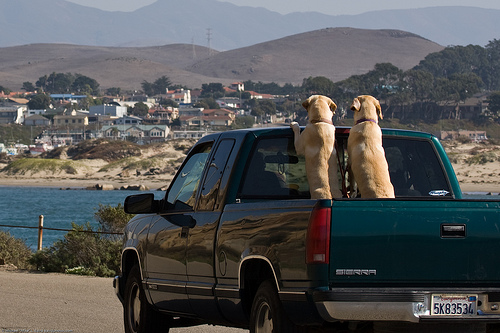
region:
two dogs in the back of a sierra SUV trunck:
[295, 88, 415, 214]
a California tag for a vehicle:
[431, 287, 493, 319]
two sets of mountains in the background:
[0, 0, 455, 100]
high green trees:
[290, 45, 498, 128]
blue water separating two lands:
[0, 189, 161, 254]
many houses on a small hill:
[0, 73, 235, 146]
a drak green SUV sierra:
[110, 105, 487, 321]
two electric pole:
[187, 20, 213, 65]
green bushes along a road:
[2, 198, 131, 269]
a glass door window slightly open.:
[150, 142, 225, 236]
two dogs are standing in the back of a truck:
[285, 89, 404, 198]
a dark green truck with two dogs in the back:
[101, 89, 498, 329]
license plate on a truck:
[422, 289, 482, 320]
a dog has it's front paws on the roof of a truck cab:
[288, 91, 347, 200]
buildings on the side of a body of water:
[0, 78, 306, 163]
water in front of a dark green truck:
[1, 179, 168, 255]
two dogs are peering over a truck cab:
[283, 91, 403, 202]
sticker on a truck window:
[424, 186, 451, 200]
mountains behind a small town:
[0, 0, 499, 82]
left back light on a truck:
[300, 204, 335, 270]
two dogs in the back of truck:
[270, 75, 446, 214]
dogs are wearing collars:
[298, 97, 389, 160]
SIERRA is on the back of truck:
[213, 200, 423, 297]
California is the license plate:
[426, 284, 494, 331]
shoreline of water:
[11, 164, 110, 202]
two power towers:
[184, 22, 236, 75]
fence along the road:
[13, 209, 120, 284]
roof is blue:
[54, 84, 96, 109]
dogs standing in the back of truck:
[278, 91, 427, 228]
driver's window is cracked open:
[173, 129, 212, 183]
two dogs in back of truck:
[293, 90, 400, 198]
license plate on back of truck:
[405, 280, 479, 315]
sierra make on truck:
[326, 263, 378, 282]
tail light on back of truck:
[308, 205, 332, 271]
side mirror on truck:
[120, 191, 165, 221]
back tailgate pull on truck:
[426, 216, 474, 236]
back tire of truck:
[236, 289, 288, 331]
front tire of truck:
[108, 275, 160, 326]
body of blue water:
[0, 176, 87, 222]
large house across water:
[106, 122, 168, 135]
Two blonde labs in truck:
[281, 81, 414, 200]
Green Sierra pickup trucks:
[73, 104, 495, 319]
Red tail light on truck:
[301, 205, 331, 275]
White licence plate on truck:
[418, 289, 497, 328]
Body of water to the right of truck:
[10, 176, 322, 282]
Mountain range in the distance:
[3, 7, 494, 95]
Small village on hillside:
[3, 60, 373, 154]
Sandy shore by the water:
[3, 149, 497, 205]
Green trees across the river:
[389, 35, 496, 90]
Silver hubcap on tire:
[124, 278, 154, 320]